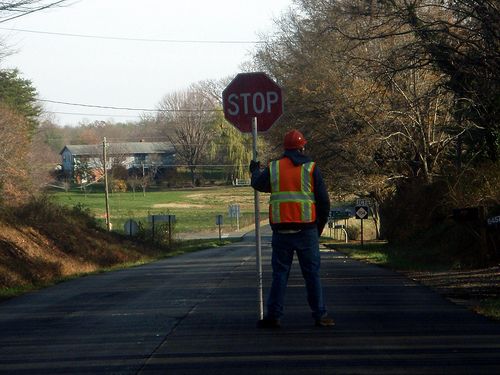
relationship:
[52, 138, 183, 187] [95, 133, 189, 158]
building has roof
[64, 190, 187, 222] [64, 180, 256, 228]
grass on field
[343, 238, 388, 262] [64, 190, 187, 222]
grass on grass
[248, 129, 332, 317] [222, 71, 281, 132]
man holding sign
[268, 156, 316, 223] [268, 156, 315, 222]
vest has stripes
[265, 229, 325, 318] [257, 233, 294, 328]
jeans on leg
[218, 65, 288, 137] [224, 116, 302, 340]
sign on pole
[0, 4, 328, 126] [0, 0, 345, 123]
cloud on sky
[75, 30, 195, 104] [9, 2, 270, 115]
white clouds in sky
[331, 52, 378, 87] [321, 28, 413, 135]
leaves on tree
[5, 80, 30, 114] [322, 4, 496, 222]
leaves on tree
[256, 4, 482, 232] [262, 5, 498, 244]
leaves on tree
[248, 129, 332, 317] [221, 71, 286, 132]
man holds stop sign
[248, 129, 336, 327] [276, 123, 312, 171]
man has head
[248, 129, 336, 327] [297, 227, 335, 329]
man has leg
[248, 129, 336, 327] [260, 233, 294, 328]
man has leg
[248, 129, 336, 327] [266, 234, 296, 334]
man has leg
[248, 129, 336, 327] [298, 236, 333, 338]
man has leg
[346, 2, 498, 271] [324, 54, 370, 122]
tree has leaves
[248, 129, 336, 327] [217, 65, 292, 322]
man holds stop sign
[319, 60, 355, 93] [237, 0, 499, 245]
leaves on tree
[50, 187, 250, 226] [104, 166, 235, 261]
grass has grass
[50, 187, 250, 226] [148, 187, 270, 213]
grass has dirt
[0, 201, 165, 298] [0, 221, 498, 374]
hill beside road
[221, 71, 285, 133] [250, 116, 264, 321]
sign on pole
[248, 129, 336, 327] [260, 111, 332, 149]
man wearing hat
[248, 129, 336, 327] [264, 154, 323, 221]
man wearing vest